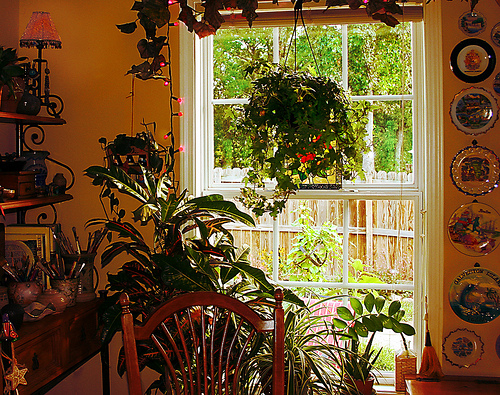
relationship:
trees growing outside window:
[210, 32, 408, 172] [190, 18, 416, 373]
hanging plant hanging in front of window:
[231, 57, 361, 218] [202, 23, 428, 366]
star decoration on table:
[0, 344, 45, 387] [1, 252, 109, 382]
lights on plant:
[159, 68, 200, 142] [79, 114, 194, 183]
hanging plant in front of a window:
[231, 57, 361, 218] [176, 2, 446, 389]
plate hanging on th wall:
[447, 35, 487, 87] [412, 30, 484, 382]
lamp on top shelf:
[16, 18, 65, 117] [7, 84, 74, 259]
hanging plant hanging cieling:
[231, 57, 361, 218] [8, 1, 484, 31]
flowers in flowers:
[242, 64, 363, 197] [42, 228, 103, 278]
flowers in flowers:
[242, 64, 363, 197] [303, 274, 412, 347]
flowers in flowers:
[242, 64, 363, 197] [123, 160, 244, 287]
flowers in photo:
[242, 64, 363, 197] [7, 9, 478, 390]